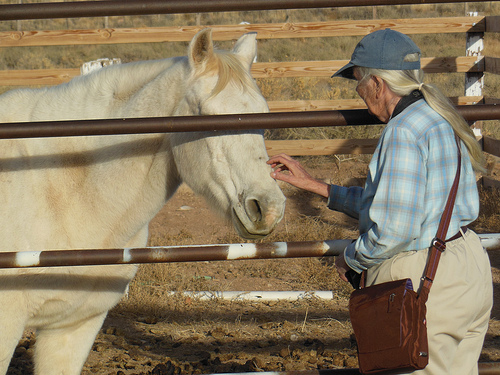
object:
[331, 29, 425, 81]
baseball cap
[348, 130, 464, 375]
messenger bag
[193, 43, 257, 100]
hair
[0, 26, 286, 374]
horse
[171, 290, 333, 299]
pole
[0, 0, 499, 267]
fence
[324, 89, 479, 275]
shirt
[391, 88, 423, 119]
collar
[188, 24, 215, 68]
ear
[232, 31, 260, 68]
ear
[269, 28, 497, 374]
woman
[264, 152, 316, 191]
right hand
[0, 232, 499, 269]
bar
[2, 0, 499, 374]
field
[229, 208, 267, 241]
jaw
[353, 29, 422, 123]
woman's head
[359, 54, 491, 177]
hair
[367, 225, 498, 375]
pants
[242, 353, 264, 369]
mud clump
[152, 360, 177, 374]
mud clump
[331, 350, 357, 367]
mud clump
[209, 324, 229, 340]
mud clump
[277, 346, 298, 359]
mud clump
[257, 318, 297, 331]
mud clump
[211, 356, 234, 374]
mud clump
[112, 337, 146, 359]
mud clump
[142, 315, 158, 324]
mud clump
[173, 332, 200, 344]
mud clump